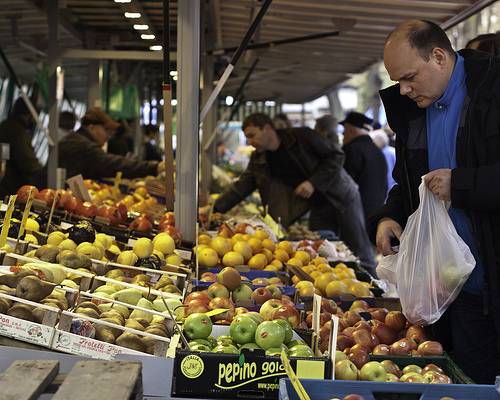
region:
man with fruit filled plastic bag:
[374, 17, 498, 382]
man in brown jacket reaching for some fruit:
[198, 111, 362, 231]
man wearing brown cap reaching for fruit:
[56, 106, 175, 183]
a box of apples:
[174, 311, 326, 398]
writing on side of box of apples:
[211, 355, 279, 382]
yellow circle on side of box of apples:
[178, 353, 201, 378]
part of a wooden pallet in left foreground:
[0, 358, 141, 398]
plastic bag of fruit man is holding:
[376, 175, 477, 327]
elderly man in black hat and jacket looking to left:
[337, 109, 388, 212]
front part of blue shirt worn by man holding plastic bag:
[428, 108, 458, 167]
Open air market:
[11, 20, 465, 399]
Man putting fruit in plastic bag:
[372, 16, 497, 342]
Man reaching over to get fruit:
[228, 103, 379, 249]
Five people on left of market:
[12, 88, 172, 173]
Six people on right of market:
[229, 20, 490, 294]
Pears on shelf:
[7, 279, 180, 361]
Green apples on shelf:
[186, 316, 310, 370]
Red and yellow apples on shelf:
[186, 275, 294, 320]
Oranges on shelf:
[196, 231, 373, 291]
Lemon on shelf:
[22, 215, 181, 260]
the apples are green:
[174, 308, 251, 350]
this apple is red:
[370, 320, 406, 343]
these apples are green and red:
[357, 355, 428, 380]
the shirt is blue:
[428, 120, 448, 140]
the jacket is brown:
[292, 142, 324, 162]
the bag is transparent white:
[407, 241, 448, 272]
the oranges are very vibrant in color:
[304, 254, 350, 294]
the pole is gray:
[171, 82, 224, 206]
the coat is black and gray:
[396, 127, 426, 178]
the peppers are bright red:
[83, 196, 145, 228]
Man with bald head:
[376, 18, 454, 113]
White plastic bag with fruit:
[401, 173, 471, 323]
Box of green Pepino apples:
[179, 314, 304, 378]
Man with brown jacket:
[228, 116, 362, 216]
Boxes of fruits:
[33, 184, 168, 264]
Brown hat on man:
[83, 105, 122, 132]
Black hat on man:
[340, 108, 375, 133]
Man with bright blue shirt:
[418, 61, 475, 199]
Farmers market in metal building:
[42, 4, 342, 314]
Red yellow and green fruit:
[11, 182, 263, 342]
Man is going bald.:
[397, 11, 431, 82]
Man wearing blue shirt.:
[434, 124, 451, 161]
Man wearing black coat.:
[460, 137, 492, 210]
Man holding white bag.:
[393, 205, 450, 295]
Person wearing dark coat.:
[288, 138, 323, 188]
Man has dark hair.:
[243, 103, 275, 130]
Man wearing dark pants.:
[346, 200, 378, 255]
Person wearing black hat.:
[338, 103, 382, 143]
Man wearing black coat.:
[353, 142, 393, 197]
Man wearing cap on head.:
[71, 94, 134, 150]